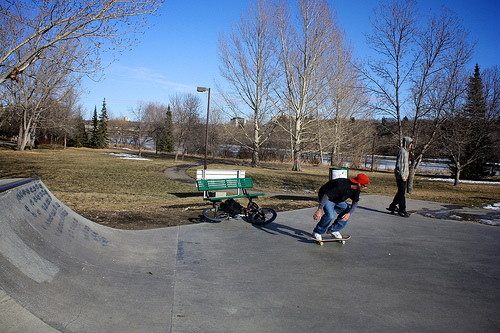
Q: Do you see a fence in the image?
A: No, there are no fences.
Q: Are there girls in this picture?
A: No, there are no girls.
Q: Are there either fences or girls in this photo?
A: No, there are no girls or fences.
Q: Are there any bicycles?
A: Yes, there is a bicycle.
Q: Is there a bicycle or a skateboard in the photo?
A: Yes, there is a bicycle.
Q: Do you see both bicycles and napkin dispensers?
A: No, there is a bicycle but no napkin dispensers.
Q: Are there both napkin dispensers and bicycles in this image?
A: No, there is a bicycle but no napkin dispensers.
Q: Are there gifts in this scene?
A: No, there are no gifts.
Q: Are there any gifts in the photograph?
A: No, there are no gifts.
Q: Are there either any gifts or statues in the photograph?
A: No, there are no gifts or statues.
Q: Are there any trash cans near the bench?
A: No, there is a bicycle near the bench.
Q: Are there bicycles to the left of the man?
A: Yes, there is a bicycle to the left of the man.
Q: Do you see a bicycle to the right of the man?
A: No, the bicycle is to the left of the man.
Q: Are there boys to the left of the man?
A: No, there is a bicycle to the left of the man.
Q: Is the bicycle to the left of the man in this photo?
A: Yes, the bicycle is to the left of the man.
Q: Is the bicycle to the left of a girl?
A: No, the bicycle is to the left of the man.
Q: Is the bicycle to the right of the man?
A: No, the bicycle is to the left of the man.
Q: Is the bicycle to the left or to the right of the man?
A: The bicycle is to the left of the man.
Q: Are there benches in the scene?
A: Yes, there is a bench.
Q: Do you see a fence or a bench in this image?
A: Yes, there is a bench.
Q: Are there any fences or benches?
A: Yes, there is a bench.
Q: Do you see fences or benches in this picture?
A: Yes, there is a bench.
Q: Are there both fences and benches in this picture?
A: No, there is a bench but no fences.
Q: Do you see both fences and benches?
A: No, there is a bench but no fences.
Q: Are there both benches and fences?
A: No, there is a bench but no fences.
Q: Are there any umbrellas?
A: No, there are no umbrellas.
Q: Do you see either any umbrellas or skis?
A: No, there are no umbrellas or skis.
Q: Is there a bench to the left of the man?
A: Yes, there is a bench to the left of the man.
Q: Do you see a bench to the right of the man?
A: No, the bench is to the left of the man.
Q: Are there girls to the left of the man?
A: No, there is a bench to the left of the man.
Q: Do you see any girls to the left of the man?
A: No, there is a bench to the left of the man.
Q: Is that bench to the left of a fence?
A: No, the bench is to the left of a man.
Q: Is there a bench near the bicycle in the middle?
A: Yes, there is a bench near the bicycle.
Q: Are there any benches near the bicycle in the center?
A: Yes, there is a bench near the bicycle.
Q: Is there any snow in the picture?
A: Yes, there is snow.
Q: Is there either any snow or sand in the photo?
A: Yes, there is snow.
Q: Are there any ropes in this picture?
A: No, there are no ropes.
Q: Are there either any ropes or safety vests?
A: No, there are no ropes or safety vests.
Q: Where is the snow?
A: The snow is on the ground.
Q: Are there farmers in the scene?
A: No, there are no farmers.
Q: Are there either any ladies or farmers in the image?
A: No, there are no farmers or ladies.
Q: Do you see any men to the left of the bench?
A: No, the man is to the right of the bench.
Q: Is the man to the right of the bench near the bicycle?
A: Yes, the man is to the right of the bench.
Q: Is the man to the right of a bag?
A: No, the man is to the right of the bench.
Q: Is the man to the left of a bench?
A: No, the man is to the right of a bench.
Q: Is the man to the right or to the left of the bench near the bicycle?
A: The man is to the right of the bench.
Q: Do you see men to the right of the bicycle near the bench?
A: Yes, there is a man to the right of the bicycle.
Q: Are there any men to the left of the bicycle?
A: No, the man is to the right of the bicycle.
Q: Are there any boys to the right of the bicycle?
A: No, there is a man to the right of the bicycle.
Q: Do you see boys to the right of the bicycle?
A: No, there is a man to the right of the bicycle.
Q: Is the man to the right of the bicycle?
A: Yes, the man is to the right of the bicycle.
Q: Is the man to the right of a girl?
A: No, the man is to the right of the bicycle.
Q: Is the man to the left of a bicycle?
A: No, the man is to the right of a bicycle.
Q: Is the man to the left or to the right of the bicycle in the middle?
A: The man is to the right of the bicycle.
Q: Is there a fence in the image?
A: No, there are no fences.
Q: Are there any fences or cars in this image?
A: No, there are no fences or cars.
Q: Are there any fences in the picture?
A: No, there are no fences.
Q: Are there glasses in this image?
A: No, there are no glasses.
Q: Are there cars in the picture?
A: No, there are no cars.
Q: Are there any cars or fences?
A: No, there are no cars or fences.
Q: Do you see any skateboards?
A: Yes, there is a skateboard.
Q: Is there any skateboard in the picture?
A: Yes, there is a skateboard.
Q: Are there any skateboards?
A: Yes, there is a skateboard.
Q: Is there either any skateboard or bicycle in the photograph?
A: Yes, there is a skateboard.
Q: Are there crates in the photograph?
A: No, there are no crates.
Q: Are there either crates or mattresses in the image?
A: No, there are no crates or mattresses.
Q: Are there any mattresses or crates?
A: No, there are no crates or mattresses.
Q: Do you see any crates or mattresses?
A: No, there are no crates or mattresses.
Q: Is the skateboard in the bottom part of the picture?
A: Yes, the skateboard is in the bottom of the image.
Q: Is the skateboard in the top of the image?
A: No, the skateboard is in the bottom of the image.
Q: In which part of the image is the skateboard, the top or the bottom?
A: The skateboard is in the bottom of the image.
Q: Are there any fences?
A: No, there are no fences.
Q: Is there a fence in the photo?
A: No, there are no fences.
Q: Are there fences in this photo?
A: No, there are no fences.